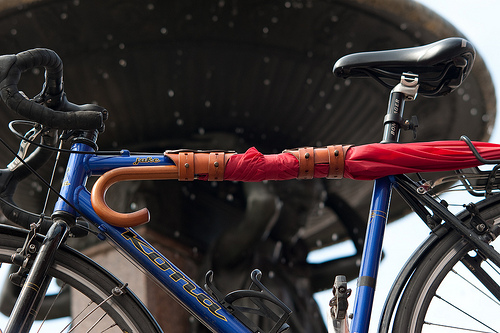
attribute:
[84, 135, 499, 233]
umbrella — closed, red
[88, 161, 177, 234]
handle — brown, wood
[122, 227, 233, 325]
lettering — black, yellow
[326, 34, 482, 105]
seat — black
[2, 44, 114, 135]
handles — bicycle, black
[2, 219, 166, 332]
tire — black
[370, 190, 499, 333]
tire — black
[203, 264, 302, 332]
holder — black, water, bottle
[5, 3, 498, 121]
structure — grey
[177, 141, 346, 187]
straps — brown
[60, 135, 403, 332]
frame — blue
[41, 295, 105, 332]
spokes — metal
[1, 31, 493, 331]
bike — blue, parked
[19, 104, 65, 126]
tape — black